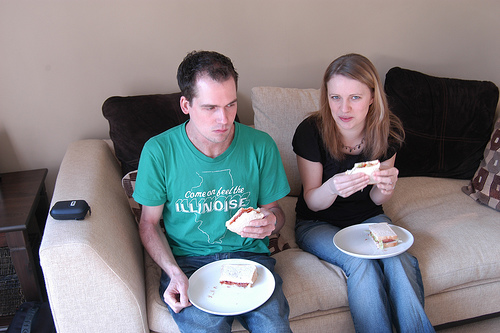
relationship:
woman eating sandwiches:
[292, 52, 434, 332] [195, 143, 396, 253]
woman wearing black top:
[292, 56, 443, 332] [304, 126, 402, 218]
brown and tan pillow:
[478, 140, 498, 213] [470, 88, 499, 210]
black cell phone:
[49, 198, 101, 233] [49, 198, 96, 220]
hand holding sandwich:
[351, 155, 372, 200] [350, 154, 381, 192]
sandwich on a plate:
[350, 154, 381, 192] [186, 255, 273, 316]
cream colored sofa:
[70, 145, 122, 201] [43, 74, 471, 332]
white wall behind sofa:
[74, 20, 155, 70] [43, 74, 471, 332]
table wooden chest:
[0, 167, 47, 332] [4, 134, 52, 301]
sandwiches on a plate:
[195, 143, 396, 253] [186, 255, 273, 316]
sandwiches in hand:
[195, 143, 396, 253] [351, 155, 372, 200]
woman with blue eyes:
[292, 56, 443, 332] [330, 85, 366, 104]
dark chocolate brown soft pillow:
[112, 90, 160, 131] [470, 88, 499, 210]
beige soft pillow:
[273, 96, 292, 135] [470, 88, 499, 210]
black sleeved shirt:
[49, 198, 101, 233] [304, 126, 402, 218]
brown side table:
[478, 140, 498, 213] [0, 167, 47, 332]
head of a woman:
[319, 41, 392, 159] [292, 56, 443, 332]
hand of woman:
[351, 155, 372, 200] [292, 56, 443, 332]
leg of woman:
[348, 270, 391, 326] [292, 56, 443, 332]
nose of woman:
[341, 96, 351, 124] [292, 56, 443, 332]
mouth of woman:
[338, 110, 356, 125] [292, 56, 443, 332]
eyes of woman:
[330, 85, 366, 104] [292, 56, 443, 332]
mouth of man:
[338, 110, 356, 125] [197, 88, 233, 147]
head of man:
[319, 41, 392, 159] [197, 88, 233, 147]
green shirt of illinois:
[155, 132, 288, 233] [170, 168, 264, 238]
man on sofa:
[197, 88, 233, 147] [38, 65, 499, 332]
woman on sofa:
[292, 56, 443, 332] [38, 65, 499, 332]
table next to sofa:
[8, 175, 47, 307] [38, 65, 499, 332]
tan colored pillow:
[258, 86, 301, 145] [470, 88, 499, 210]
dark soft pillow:
[414, 89, 491, 176] [470, 88, 499, 210]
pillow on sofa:
[470, 88, 499, 210] [38, 65, 499, 332]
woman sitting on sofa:
[292, 52, 434, 332] [38, 65, 499, 332]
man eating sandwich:
[197, 88, 233, 147] [350, 154, 381, 192]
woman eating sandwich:
[292, 56, 443, 332] [350, 154, 381, 192]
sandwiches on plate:
[195, 143, 396, 253] [186, 255, 273, 316]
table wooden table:
[0, 167, 47, 332] [8, 175, 47, 307]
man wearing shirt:
[197, 88, 233, 147] [155, 132, 288, 233]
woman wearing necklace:
[292, 56, 443, 332] [345, 141, 376, 163]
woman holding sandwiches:
[292, 56, 443, 332] [195, 143, 396, 253]